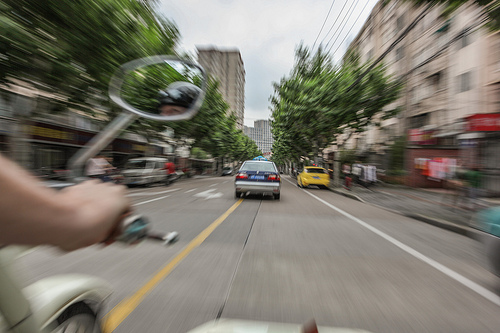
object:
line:
[273, 170, 500, 314]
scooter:
[0, 53, 380, 330]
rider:
[0, 148, 133, 256]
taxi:
[293, 163, 334, 190]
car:
[233, 159, 282, 201]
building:
[336, 1, 498, 193]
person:
[162, 157, 179, 187]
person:
[81, 146, 117, 188]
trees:
[283, 55, 374, 176]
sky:
[147, 0, 379, 128]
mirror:
[106, 53, 208, 124]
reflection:
[122, 62, 200, 117]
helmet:
[153, 79, 202, 113]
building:
[194, 45, 247, 155]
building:
[240, 117, 273, 157]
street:
[0, 156, 496, 332]